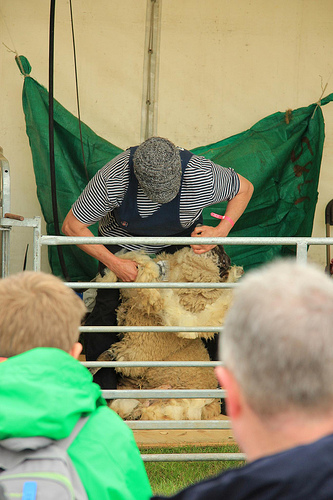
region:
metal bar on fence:
[42, 231, 295, 249]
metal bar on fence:
[63, 280, 238, 290]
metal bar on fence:
[78, 324, 220, 333]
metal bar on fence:
[100, 388, 224, 400]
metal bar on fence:
[121, 418, 229, 433]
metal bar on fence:
[137, 452, 244, 461]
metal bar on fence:
[78, 358, 219, 367]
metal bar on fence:
[101, 389, 227, 398]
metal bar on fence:
[306, 235, 332, 246]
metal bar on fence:
[295, 240, 308, 263]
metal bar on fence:
[32, 219, 41, 270]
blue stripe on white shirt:
[180, 166, 206, 179]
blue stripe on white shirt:
[112, 154, 134, 163]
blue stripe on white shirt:
[106, 166, 122, 181]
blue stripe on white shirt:
[105, 183, 129, 194]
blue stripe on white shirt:
[96, 190, 120, 209]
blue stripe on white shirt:
[79, 198, 94, 215]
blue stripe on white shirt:
[180, 204, 202, 215]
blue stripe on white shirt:
[134, 194, 147, 213]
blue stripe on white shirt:
[102, 224, 119, 233]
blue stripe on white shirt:
[131, 243, 150, 260]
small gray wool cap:
[122, 135, 184, 194]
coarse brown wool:
[128, 337, 181, 357]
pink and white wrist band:
[203, 206, 245, 224]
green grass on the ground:
[156, 464, 185, 478]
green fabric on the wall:
[218, 107, 282, 167]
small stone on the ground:
[156, 428, 175, 438]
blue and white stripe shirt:
[187, 170, 221, 201]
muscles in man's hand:
[60, 222, 106, 241]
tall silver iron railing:
[108, 227, 204, 406]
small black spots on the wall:
[201, 20, 256, 79]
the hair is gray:
[252, 280, 319, 405]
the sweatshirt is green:
[9, 363, 126, 498]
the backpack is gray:
[5, 437, 82, 493]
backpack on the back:
[0, 359, 143, 498]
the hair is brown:
[5, 291, 74, 356]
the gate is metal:
[104, 325, 237, 466]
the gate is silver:
[84, 325, 243, 468]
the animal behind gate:
[108, 245, 246, 458]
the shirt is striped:
[98, 149, 212, 253]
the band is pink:
[217, 214, 236, 228]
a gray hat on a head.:
[132, 132, 181, 200]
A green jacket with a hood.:
[0, 346, 155, 498]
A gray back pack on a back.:
[0, 413, 92, 498]